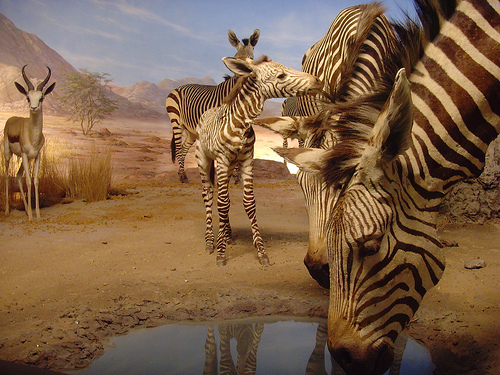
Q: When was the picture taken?
A: Daytime.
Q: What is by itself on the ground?
A: Bare tree.